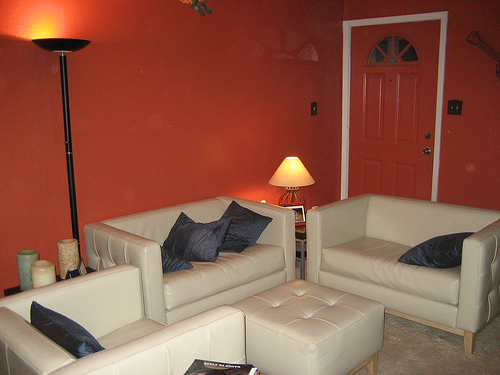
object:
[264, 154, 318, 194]
shade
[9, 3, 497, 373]
room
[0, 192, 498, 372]
furniture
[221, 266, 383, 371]
ottoman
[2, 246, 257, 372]
couches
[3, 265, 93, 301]
table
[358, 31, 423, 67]
insert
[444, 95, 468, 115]
switch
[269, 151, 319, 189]
white shade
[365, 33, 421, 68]
window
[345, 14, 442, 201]
red door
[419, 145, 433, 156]
door knob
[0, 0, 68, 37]
light glare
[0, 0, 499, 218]
red wall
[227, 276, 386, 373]
white ottoman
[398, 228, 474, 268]
pillow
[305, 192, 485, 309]
couch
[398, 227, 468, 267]
blue pillow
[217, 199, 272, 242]
blue pillows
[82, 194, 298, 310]
couch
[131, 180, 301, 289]
pillows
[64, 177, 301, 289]
sofa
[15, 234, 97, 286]
candles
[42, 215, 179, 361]
table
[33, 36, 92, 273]
floor lamp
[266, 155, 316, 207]
lamp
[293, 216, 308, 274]
table